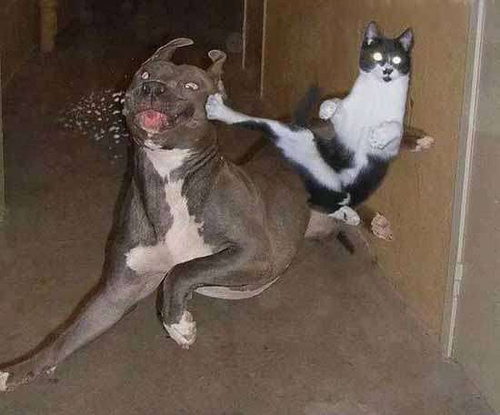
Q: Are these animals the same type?
A: No, they are dogs and cats.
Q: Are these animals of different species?
A: Yes, they are dogs and cats.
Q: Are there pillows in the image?
A: No, there are no pillows.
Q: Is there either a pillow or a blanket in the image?
A: No, there are no pillows or blankets.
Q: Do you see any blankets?
A: No, there are no blankets.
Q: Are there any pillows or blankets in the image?
A: No, there are no blankets or pillows.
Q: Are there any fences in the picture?
A: No, there are no fences.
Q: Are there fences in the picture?
A: No, there are no fences.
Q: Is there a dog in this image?
A: Yes, there is a dog.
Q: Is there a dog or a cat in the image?
A: Yes, there is a dog.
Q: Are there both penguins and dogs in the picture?
A: No, there is a dog but no penguins.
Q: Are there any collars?
A: No, there are no collars.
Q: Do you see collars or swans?
A: No, there are no collars or swans.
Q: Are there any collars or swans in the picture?
A: No, there are no collars or swans.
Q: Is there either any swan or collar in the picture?
A: No, there are no collars or swans.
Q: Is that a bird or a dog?
A: That is a dog.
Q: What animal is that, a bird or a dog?
A: That is a dog.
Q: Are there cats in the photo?
A: Yes, there is a cat.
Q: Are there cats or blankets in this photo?
A: Yes, there is a cat.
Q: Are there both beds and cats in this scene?
A: No, there is a cat but no beds.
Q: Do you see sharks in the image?
A: No, there are no sharks.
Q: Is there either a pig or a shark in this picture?
A: No, there are no sharks or pigs.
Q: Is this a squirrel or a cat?
A: This is a cat.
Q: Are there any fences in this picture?
A: No, there are no fences.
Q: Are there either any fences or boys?
A: No, there are no fences or boys.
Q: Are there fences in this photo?
A: No, there are no fences.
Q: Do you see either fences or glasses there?
A: No, there are no fences or glasses.